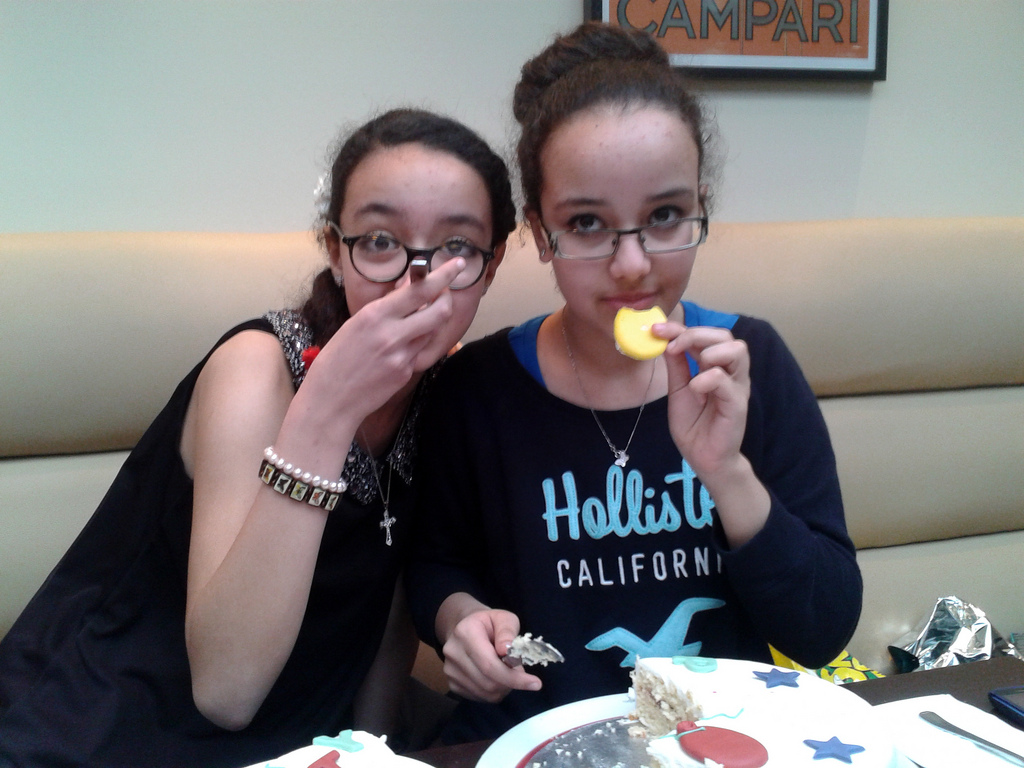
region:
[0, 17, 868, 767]
two girls wearing glasses and eating a snack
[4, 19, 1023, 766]
beige bench with two people sitting on it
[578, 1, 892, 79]
an orange sign with the word campari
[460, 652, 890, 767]
a plate with half a cake on top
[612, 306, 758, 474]
small yellow cake held in hand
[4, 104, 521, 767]
girl wearing pearl bracelet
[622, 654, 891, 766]
white cake with blue stars and a red oval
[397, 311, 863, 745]
navy shirt with the word Holliste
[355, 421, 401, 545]
necklace with a cross pendant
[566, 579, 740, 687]
the logo is blue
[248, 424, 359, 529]
the bracelets are black and pearl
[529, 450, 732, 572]
the letters are blue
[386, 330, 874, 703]
the shirt is blue with blue letters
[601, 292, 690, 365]
the cookie has a bite out of it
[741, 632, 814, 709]
the star is blue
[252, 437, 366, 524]
Two bracelets worn by girl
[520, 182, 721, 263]
Glasses worn by girl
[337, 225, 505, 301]
Eyeglasses worn by girl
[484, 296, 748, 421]
Blue shirt under sweatshirt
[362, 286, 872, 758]
Black sweatshirt with Hollister California on front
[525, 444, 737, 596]
Hollister California on Sweatshirt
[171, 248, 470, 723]
Right arm of girl on the left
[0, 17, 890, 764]
Two girls sitting at a booth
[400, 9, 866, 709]
Girl eating a cracker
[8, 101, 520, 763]
Girl with a spoon in her mouth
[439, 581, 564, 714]
Dirty spoon in the girl's hand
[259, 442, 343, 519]
Bracelet on the girls arm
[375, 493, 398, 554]
Cross on a chain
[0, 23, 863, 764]
Two brunettes wearing eyeglasses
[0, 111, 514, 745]
girl in a black blouse wearing eye glasses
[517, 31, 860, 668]
girl in a black sweat shirt wearing eye glasses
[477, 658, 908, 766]
white cake on a serving dish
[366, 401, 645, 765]
girl holding a cake knife in her right hand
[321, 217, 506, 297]
round black framed eye glasses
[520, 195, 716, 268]
rectangular black framed eye glasses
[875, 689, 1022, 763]
white paper napkin on the dining table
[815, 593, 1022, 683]
gift wrapping piled up on the dining table booth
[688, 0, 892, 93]
framed art on the wall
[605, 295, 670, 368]
cake decor being eaten by girl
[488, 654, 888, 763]
cut birthday cake with pieces missing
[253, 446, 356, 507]
two bracelets on girls wrist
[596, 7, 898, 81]
art on wall with campari written on it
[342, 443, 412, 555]
silver cross necklace on thin chain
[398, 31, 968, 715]
girl eating a cookie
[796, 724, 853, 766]
blue star on cake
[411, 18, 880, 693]
girl with hair in a bun.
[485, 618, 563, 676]
fork with cake on it.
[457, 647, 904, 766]
a plate with a cake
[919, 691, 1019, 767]
utensil laying beside cake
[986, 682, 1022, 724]
cell phone on table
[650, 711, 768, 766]
red circle on cake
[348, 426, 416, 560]
silver cross on chain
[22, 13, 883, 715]
two girls wearing glasses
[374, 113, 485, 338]
a girl wearing glasses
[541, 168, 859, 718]
a girl wearing a shirt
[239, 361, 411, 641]
a girl wearing a bracelet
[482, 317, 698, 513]
a girl wearing a knecklace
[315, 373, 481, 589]
a girl wearing a knecklace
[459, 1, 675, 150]
a girl with her hair in the bun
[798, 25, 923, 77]
a picture on the wall